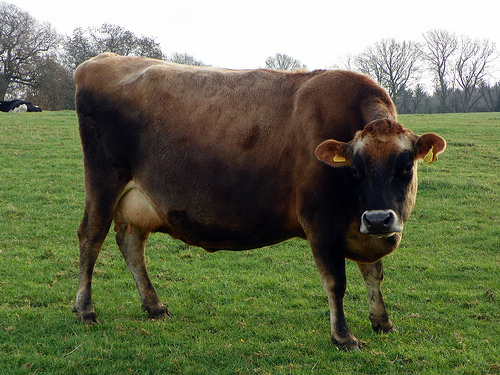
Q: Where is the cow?
A: On the grass.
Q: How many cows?
A: 1.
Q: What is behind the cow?
A: Trees.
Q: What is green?
A: The grass.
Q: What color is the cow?
A: Brown.